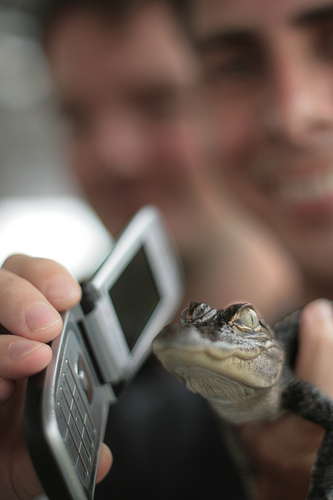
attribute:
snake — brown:
[171, 292, 324, 435]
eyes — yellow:
[235, 305, 262, 334]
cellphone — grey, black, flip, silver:
[59, 217, 153, 487]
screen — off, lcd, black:
[107, 229, 156, 330]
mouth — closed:
[155, 320, 258, 375]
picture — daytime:
[1, 5, 328, 499]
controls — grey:
[50, 364, 95, 466]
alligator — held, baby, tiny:
[180, 315, 329, 409]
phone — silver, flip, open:
[33, 216, 149, 466]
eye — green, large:
[230, 311, 260, 328]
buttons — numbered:
[61, 369, 91, 460]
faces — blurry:
[160, 49, 329, 139]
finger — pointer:
[19, 247, 76, 303]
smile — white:
[263, 152, 332, 199]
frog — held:
[156, 303, 299, 403]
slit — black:
[249, 310, 255, 326]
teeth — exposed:
[291, 178, 332, 203]